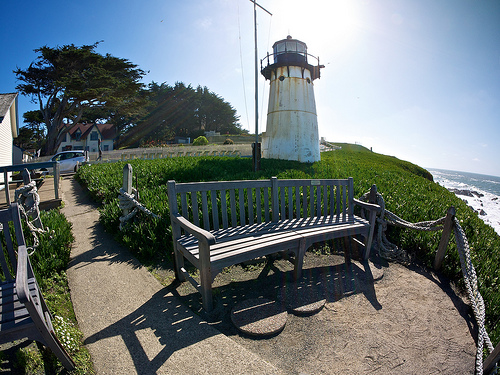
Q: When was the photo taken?
A: Daytime.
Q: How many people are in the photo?
A: None.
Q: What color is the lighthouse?
A: White.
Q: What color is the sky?
A: Blue.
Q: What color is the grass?
A: Green.